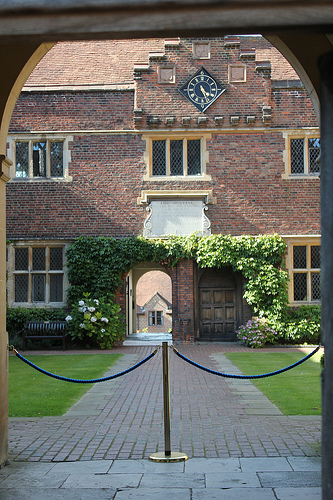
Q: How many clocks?
A: One.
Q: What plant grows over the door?
A: Ivy.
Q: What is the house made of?
A: Bricks.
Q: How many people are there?
A: None.